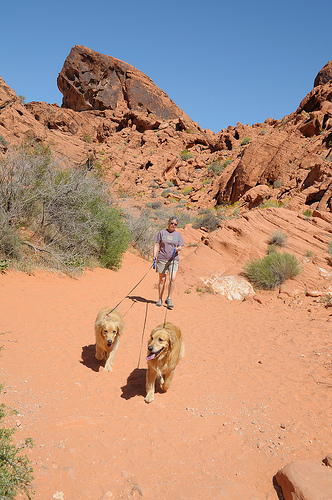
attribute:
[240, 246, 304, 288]
bush — dry, green, dark, small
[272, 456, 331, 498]
rock — brown, small, red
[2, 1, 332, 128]
sky — light, blue, bright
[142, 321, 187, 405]
dog — dark, brown, walking, golden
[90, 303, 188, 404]
dogs — walking, golden, brown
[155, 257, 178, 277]
shorts — light, beige, tan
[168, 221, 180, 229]
sunglasses — dark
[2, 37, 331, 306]
rocks — big, large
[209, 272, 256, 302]
rock — white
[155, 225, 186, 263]
shirt — purple, dark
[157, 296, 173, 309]
shoe — tan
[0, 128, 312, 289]
bushes — scattered, green